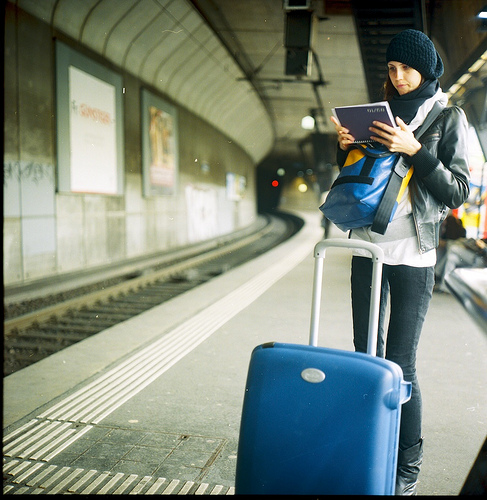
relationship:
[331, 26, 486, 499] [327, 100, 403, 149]
woman holding notebook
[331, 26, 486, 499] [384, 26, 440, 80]
woman wearing hat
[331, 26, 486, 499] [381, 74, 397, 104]
woman has hair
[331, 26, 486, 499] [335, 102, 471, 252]
woman wearing jacket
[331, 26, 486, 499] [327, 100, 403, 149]
girl looking at book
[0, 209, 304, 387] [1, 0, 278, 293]
train tracks next to wall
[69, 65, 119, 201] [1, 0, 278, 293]
advertisement on wall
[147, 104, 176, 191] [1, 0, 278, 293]
advertisement on wall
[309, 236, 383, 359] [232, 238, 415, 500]
handle on top of suitcase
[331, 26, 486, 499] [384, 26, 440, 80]
girl wearing a hat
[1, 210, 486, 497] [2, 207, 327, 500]
cement has bumps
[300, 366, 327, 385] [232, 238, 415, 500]
label on suitcase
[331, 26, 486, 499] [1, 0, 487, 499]
woman at train station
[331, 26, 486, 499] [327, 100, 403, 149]
woman holding book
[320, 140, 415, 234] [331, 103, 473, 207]
bag in womans arms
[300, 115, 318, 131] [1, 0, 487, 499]
lights in train station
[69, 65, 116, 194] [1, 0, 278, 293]
advertisement on wall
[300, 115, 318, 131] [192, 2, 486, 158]
light on ceiling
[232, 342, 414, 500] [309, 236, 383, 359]
suitcase has a handle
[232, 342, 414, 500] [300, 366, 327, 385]
suitcase has logo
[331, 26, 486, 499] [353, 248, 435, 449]
woman wearing blue jeans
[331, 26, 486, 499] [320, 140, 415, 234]
woman holding bag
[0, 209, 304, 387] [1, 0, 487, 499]
subway track in train station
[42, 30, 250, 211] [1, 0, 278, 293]
advertisement panel on wall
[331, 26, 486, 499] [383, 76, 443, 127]
woman wearing scarf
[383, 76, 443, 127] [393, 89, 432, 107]
scarf around neck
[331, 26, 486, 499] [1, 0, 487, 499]
woman standing in subway station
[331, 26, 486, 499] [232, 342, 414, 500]
woman has suitcase